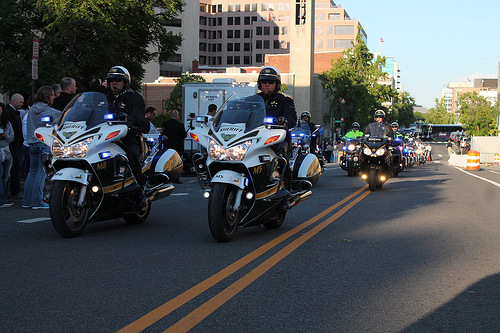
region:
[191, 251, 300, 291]
double yellow lines on the ground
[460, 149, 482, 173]
orange and white drum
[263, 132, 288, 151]
light on front of bike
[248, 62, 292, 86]
white and blue helmet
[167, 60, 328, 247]
police officer riding bike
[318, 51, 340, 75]
red bricks on the wall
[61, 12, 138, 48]
green tree in the street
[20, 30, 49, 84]
tall red and white sign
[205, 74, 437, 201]
parade of motor bikes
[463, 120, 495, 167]
tall white retaining wall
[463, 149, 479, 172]
Orange and white traffic barrel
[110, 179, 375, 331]
Double yellow lines through street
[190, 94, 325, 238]
Police motorcycle on the road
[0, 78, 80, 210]
Group of people on the side of the street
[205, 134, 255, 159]
Motorcycle headlights are on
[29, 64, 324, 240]
Pair of officers riding motorcycles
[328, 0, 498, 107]
Clear blue sky behind cityscape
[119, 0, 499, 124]
Tall city buildings in the background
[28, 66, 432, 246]
Parade of motorcycles on the road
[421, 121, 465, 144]
Large bus in the background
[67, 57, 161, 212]
police officer on motorcycle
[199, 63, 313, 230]
police officer on motorcycle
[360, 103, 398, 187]
police officer on motorcycle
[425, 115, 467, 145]
city bus in background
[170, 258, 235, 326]
yellow lines on road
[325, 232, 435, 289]
shadow of trees on road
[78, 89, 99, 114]
glass windshield on bike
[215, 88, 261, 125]
glass windshield on bike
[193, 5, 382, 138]
tall building in background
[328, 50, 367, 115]
trees along side road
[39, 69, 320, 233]
Motorbikes in the picture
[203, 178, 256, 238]
A motorbike wheel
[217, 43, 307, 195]
Police officer in the photo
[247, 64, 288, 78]
A helmet in the photo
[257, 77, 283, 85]
Eyeglasses in the photo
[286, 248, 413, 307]
Road with tarmac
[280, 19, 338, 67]
A building in the photo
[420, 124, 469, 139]
A bus in the background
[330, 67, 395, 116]
Trees in the picture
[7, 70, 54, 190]
People standing on the roadside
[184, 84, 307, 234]
the bike is white in color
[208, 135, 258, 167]
the lights are on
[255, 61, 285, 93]
the helmet is white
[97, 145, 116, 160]
the light is blue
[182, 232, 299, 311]
the lines are yellow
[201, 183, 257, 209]
the light is on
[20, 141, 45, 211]
the jeans is blue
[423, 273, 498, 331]
shadow is on the ground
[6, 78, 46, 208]
people are spectating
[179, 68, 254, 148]
the ambulance is white